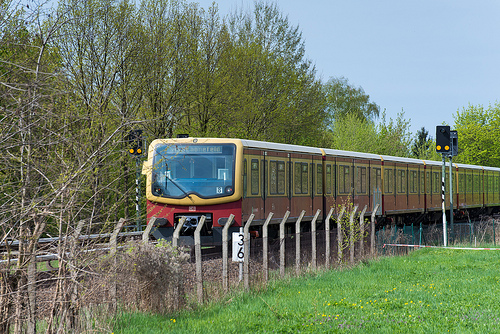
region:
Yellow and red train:
[137, 136, 497, 257]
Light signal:
[430, 120, 455, 242]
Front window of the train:
[145, 140, 235, 200]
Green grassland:
[100, 246, 497, 331]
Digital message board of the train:
[155, 140, 221, 155]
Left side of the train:
[241, 146, 496, 242]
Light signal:
[121, 120, 144, 231]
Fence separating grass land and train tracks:
[11, 203, 377, 328]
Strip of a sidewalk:
[387, 240, 494, 260]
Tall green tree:
[167, 2, 337, 144]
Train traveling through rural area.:
[12, 17, 493, 325]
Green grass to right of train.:
[141, 260, 498, 331]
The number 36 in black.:
[229, 229, 253, 271]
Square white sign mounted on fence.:
[221, 225, 262, 270]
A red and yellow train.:
[129, 105, 498, 234]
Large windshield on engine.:
[150, 129, 237, 204]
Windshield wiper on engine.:
[151, 160, 218, 205]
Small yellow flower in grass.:
[314, 276, 451, 327]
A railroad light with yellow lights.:
[431, 120, 458, 161]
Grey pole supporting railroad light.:
[430, 120, 460, 251]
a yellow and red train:
[141, 135, 498, 240]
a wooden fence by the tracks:
[11, 197, 384, 325]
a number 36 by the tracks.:
[231, 231, 251, 261]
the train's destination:
[165, 145, 223, 155]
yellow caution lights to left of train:
[126, 129, 143, 154]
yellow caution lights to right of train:
[434, 124, 451, 152]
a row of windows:
[241, 155, 499, 197]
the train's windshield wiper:
[162, 174, 194, 202]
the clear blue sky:
[298, 3, 499, 75]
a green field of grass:
[348, 256, 499, 332]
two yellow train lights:
[428, 120, 457, 164]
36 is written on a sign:
[189, 227, 264, 272]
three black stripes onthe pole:
[438, 175, 458, 214]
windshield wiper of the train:
[166, 166, 201, 200]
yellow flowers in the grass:
[339, 265, 461, 331]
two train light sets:
[117, 120, 487, 172]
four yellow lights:
[120, 142, 467, 161]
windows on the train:
[245, 150, 397, 198]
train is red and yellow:
[210, 140, 396, 223]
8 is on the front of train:
[213, 186, 243, 201]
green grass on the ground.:
[310, 278, 375, 310]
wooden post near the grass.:
[195, 217, 207, 295]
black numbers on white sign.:
[231, 231, 244, 271]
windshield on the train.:
[183, 166, 215, 179]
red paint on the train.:
[211, 207, 233, 216]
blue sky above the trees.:
[365, 30, 433, 70]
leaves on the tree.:
[344, 121, 371, 143]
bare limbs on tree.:
[60, 120, 110, 195]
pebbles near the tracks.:
[202, 256, 217, 279]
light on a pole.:
[436, 122, 449, 150]